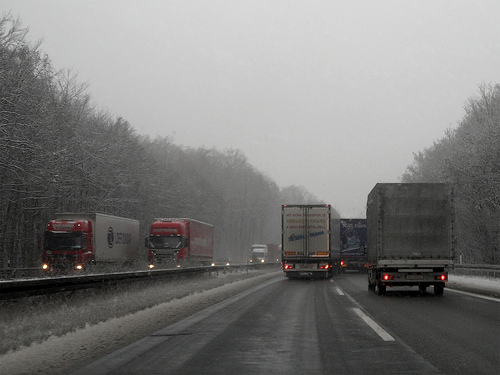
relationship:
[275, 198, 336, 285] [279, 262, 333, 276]
truck has break light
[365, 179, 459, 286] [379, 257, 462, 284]
truck has a bumper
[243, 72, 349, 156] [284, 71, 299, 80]
sky has clouds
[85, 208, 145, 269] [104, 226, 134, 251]
trailer has writing